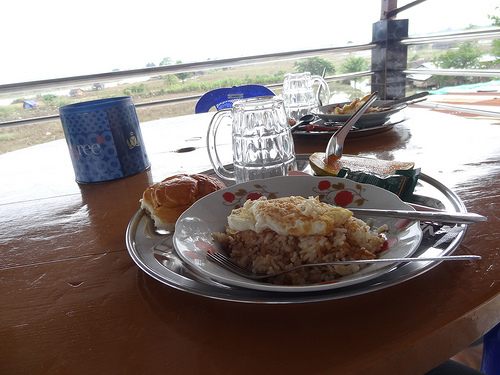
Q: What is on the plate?
A: Food.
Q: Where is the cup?
A: On the plate.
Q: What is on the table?
A: Plates.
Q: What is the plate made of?
A: Porcelain.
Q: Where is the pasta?
A: On the plate.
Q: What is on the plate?
A: Food.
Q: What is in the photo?
A: Food.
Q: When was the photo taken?
A: During the daytime.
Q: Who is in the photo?
A: No people.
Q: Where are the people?
A: None in photo.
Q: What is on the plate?
A: Food.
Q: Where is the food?
A: On a plate.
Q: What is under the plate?
A: A table.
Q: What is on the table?
A: A plate.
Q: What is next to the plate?
A: A glass.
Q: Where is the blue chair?
A: At the table.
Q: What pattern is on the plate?
A: Flowers.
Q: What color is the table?
A: Brown.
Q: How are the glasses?
A: Upside down.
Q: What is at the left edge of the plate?
A: Roll.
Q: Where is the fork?
A: On the plate.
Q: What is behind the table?
A: Rail.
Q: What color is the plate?
A: White.